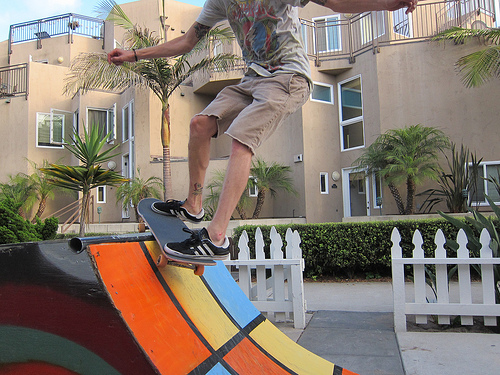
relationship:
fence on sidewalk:
[219, 225, 498, 329] [267, 312, 498, 372]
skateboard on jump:
[131, 189, 215, 276] [19, 238, 147, 283]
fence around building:
[219, 225, 498, 329] [3, 2, 497, 224]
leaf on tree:
[7, 220, 12, 224] [1, 205, 59, 242]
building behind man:
[3, 2, 497, 224] [105, 0, 418, 262]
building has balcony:
[3, 2, 497, 224] [288, 17, 410, 71]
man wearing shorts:
[102, 0, 429, 258] [184, 73, 310, 147]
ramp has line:
[5, 232, 356, 373] [189, 312, 266, 373]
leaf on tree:
[98, 138, 127, 161] [43, 122, 121, 252]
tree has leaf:
[46, 111, 129, 216] [81, 157, 95, 188]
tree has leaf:
[114, 13, 190, 209] [126, 18, 149, 44]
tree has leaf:
[350, 122, 454, 216] [387, 128, 408, 149]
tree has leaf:
[358, 119, 453, 216] [370, 107, 460, 199]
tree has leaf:
[350, 122, 454, 216] [409, 136, 416, 146]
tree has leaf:
[44, 114, 126, 223] [88, 122, 100, 148]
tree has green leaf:
[428, 10, 498, 91] [457, 41, 485, 69]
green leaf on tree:
[417, 157, 439, 179] [350, 122, 454, 216]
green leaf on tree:
[188, 51, 245, 79] [58, 3, 243, 201]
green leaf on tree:
[87, 117, 102, 147] [37, 120, 132, 238]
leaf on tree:
[411, 185, 452, 197] [413, 144, 499, 212]